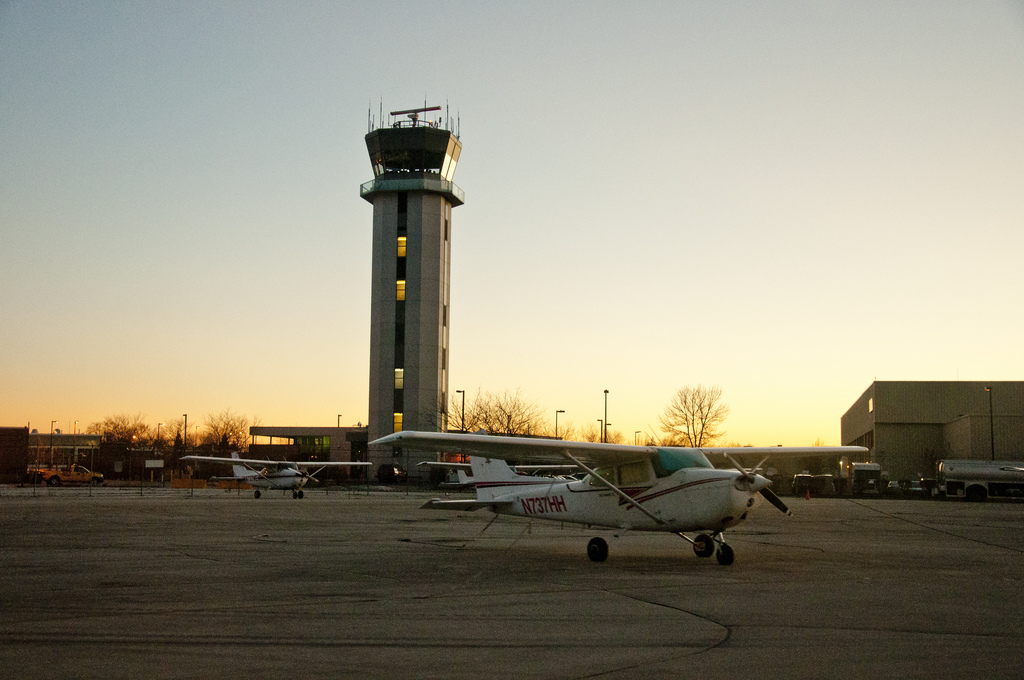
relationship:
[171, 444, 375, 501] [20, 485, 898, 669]
plane on ground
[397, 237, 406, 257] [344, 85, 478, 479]
glass on airplane tower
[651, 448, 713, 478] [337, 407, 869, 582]
glass on plane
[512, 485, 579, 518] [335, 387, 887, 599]
numbers on plane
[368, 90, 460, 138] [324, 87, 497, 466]
antennas on top of tower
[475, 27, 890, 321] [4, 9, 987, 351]
clouds in sky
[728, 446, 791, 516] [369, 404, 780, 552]
propeller of airplane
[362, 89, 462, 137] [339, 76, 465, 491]
antennas on top of tower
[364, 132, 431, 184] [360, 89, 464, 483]
wall on side of a airplane tower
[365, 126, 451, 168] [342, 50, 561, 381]
wall on side of a building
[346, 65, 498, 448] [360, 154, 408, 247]
wall on side of a building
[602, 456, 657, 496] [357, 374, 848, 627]
window on a plane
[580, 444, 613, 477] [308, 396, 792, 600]
window on a plane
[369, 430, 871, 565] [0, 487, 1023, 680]
airplane on ground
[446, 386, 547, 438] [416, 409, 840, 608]
tree behind plane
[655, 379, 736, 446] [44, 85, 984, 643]
tree in a city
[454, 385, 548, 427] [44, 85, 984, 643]
tree in a city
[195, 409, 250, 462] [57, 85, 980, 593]
tree in a city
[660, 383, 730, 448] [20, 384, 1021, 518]
tree in city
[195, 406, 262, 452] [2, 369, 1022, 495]
tree in city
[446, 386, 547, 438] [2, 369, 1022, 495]
tree in city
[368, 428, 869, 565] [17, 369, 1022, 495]
airplane on terminal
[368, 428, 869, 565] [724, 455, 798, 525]
airplane has propeller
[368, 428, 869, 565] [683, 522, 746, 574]
airplane has landing gear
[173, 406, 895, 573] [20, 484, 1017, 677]
planes in terminal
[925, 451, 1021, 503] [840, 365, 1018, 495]
truck by building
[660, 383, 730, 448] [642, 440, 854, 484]
tree behind building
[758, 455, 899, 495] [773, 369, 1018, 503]
vehicles by building